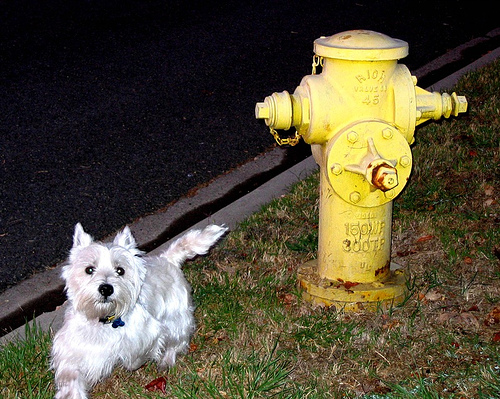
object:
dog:
[48, 221, 228, 399]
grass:
[0, 54, 499, 399]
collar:
[98, 315, 115, 324]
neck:
[82, 310, 127, 325]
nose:
[98, 284, 114, 296]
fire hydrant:
[254, 29, 469, 315]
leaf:
[145, 377, 166, 394]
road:
[0, 0, 499, 341]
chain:
[269, 127, 301, 146]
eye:
[86, 266, 93, 274]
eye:
[117, 267, 125, 275]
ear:
[73, 222, 92, 248]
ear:
[112, 224, 138, 249]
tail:
[159, 223, 228, 267]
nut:
[372, 164, 399, 192]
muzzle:
[96, 283, 115, 304]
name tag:
[112, 317, 125, 328]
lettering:
[342, 221, 385, 253]